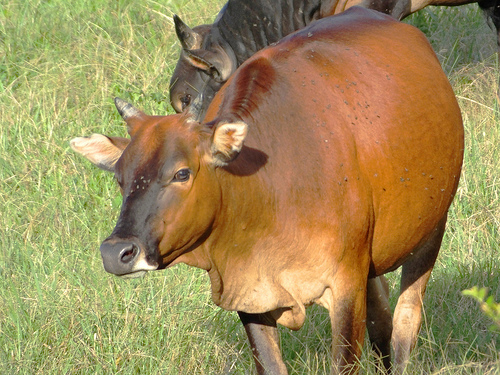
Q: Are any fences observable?
A: No, there are no fences.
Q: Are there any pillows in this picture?
A: No, there are no pillows.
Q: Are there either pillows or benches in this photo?
A: No, there are no pillows or benches.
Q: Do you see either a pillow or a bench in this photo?
A: No, there are no pillows or benches.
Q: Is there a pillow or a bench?
A: No, there are no pillows or benches.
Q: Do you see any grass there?
A: Yes, there is grass.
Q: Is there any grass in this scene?
A: Yes, there is grass.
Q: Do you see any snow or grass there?
A: Yes, there is grass.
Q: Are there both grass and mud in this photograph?
A: No, there is grass but no mud.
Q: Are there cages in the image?
A: No, there are no cages.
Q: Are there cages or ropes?
A: No, there are no cages or ropes.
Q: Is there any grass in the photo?
A: Yes, there is grass.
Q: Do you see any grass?
A: Yes, there is grass.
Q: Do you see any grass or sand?
A: Yes, there is grass.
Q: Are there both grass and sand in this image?
A: No, there is grass but no sand.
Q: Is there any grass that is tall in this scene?
A: Yes, there is tall grass.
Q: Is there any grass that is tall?
A: Yes, there is grass that is tall.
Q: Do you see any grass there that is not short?
A: Yes, there is tall grass.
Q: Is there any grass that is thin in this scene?
A: Yes, there is thin grass.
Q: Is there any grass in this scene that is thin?
A: Yes, there is grass that is thin.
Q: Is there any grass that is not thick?
A: Yes, there is thin grass.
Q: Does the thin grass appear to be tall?
A: Yes, the grass is tall.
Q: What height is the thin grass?
A: The grass is tall.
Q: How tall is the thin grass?
A: The grass is tall.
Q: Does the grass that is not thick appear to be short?
A: No, the grass is tall.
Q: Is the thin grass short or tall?
A: The grass is tall.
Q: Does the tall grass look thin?
A: Yes, the grass is thin.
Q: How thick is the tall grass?
A: The grass is thin.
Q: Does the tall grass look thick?
A: No, the grass is thin.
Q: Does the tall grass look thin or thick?
A: The grass is thin.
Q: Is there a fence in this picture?
A: No, there are no fences.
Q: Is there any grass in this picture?
A: Yes, there is grass.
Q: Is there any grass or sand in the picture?
A: Yes, there is grass.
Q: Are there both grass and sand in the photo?
A: No, there is grass but no sand.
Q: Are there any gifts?
A: No, there are no gifts.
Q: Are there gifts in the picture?
A: No, there are no gifts.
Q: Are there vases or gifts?
A: No, there are no gifts or vases.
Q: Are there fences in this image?
A: No, there are no fences.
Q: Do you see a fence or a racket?
A: No, there are no fences or rackets.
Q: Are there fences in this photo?
A: No, there are no fences.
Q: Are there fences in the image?
A: No, there are no fences.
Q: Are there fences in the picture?
A: No, there are no fences.